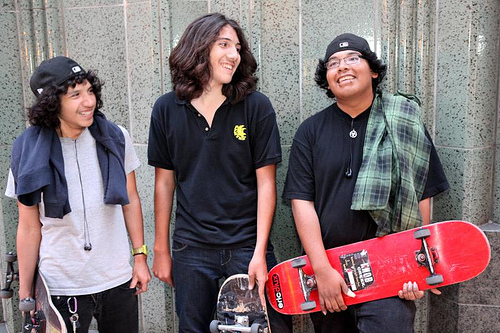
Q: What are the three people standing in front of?
A: Wall.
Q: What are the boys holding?
A: Skateboards.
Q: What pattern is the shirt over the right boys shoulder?
A: Plaid.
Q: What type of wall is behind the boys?
A: Granite.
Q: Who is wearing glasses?
A: Boy on right.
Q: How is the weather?
A: Sunny.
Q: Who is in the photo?
A: Men and a woman.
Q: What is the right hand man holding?
A: A red skateboard.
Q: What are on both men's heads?
A: Caps.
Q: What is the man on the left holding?
A: A skateboard.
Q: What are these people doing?
A: Skateboarding.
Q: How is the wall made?
A: Of marble.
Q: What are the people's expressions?
A: Smiling.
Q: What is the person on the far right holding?
A: Skateboard.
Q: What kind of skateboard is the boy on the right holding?
A: Red skateboard.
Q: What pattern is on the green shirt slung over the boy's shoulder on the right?
A: Plaid.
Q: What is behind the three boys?
A: Wall.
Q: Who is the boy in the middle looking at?
A: The boy on the far right.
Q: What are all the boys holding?
A: Skateboards.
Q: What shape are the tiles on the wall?
A: Rectangular.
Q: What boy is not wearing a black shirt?
A: Boy on the far left.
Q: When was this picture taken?
A: Daytime.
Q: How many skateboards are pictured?
A: 3.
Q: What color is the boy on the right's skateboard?
A: Red.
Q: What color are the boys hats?
A: Black.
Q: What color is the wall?
A: Gray.